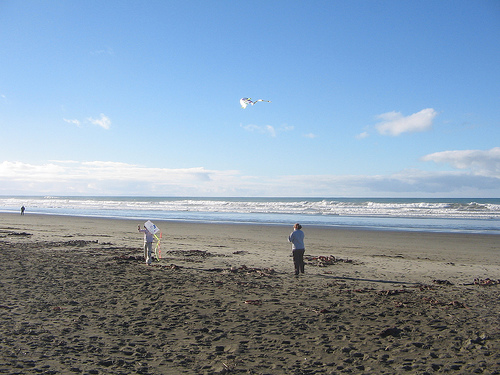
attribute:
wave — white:
[3, 193, 498, 223]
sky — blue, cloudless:
[13, 7, 186, 99]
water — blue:
[4, 197, 499, 237]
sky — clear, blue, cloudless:
[286, 6, 407, 82]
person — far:
[19, 205, 25, 215]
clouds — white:
[338, 109, 459, 184]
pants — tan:
[138, 238, 158, 260]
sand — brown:
[3, 210, 498, 372]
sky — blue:
[4, 5, 498, 195]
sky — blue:
[81, 14, 478, 178]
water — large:
[312, 207, 457, 224]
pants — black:
[288, 246, 310, 280]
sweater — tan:
[285, 229, 310, 251]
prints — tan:
[324, 284, 454, 359]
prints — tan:
[3, 237, 495, 373]